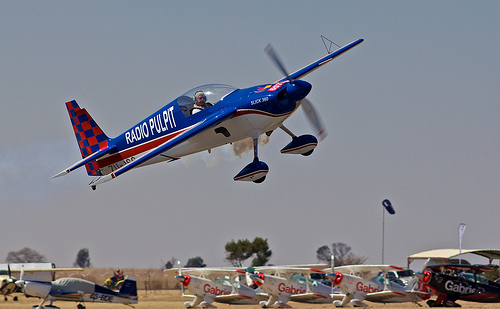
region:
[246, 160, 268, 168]
blue paint on plane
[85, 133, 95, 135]
blue paint on plane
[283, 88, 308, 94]
blue paint on plane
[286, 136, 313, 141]
blue paint on plane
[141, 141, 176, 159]
blue paint on plane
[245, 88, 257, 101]
blue paint on plane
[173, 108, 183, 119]
blue paint on plane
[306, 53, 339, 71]
blue paint on plane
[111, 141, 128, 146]
blue paint on plane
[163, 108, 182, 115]
blue paint on plane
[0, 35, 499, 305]
a small plane flies low over an airport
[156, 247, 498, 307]
planes are parked on the ground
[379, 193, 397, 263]
a dark blue wind sock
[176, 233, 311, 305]
a tree behind parked planes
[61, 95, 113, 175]
red and blue plane tail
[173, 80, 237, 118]
pilot is sitting in the cockpit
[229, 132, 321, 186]
pair of plane wheels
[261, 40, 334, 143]
plane propeller is moving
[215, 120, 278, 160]
smoke coming out of a plane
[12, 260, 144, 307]
parked plane has a plastic cover over the cockpit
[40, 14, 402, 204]
blue and red plane flying in the sky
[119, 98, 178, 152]
"radio pulpit" written on side in white letters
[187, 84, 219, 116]
pilot looking to his right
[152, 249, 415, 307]
row of identical white and orange planes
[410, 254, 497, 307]
part of a blue and orange plane in frame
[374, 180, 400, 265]
pole with a blue wind sock on it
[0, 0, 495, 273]
dark blue-grey sky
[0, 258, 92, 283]
white structure in near background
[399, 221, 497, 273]
white canopy in near background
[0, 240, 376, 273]
trees just beyond horizon line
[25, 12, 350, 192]
blue and red plane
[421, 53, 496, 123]
white clouds n blue sky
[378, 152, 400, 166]
white clouds n blue sky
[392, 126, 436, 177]
white clouds n blue sky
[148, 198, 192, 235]
white clouds n blue sky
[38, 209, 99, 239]
white clouds n blue sky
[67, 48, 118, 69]
white clouds n blue sky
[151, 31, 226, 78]
white clouds n blue sky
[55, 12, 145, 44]
white clouds n blue sky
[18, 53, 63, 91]
white clouds n blue sky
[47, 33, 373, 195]
Aircraft flying in mid air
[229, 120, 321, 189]
landing wheels of the aircraft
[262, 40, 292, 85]
Propeller blade on the nose of the aircraft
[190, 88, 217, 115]
A pilot flying the aircraft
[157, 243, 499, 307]
Group of aircraft on the field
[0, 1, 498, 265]
Clear weather in the sky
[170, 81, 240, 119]
Cockpit of the aircraft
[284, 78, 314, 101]
Nose hub of the aircraft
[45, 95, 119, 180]
Tail section of the aircraft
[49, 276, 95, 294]
Cloth cover on the cockpit of the aircraft